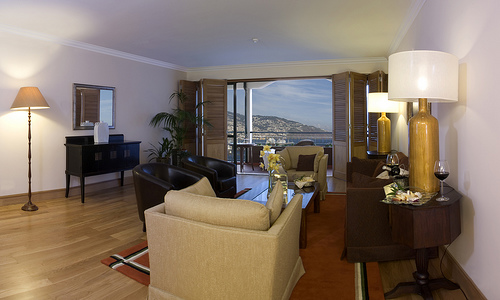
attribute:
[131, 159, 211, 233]
chair — leather, black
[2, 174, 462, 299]
floor — wood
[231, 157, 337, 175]
balcony — white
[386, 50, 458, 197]
lamp — tall, tan, gold, large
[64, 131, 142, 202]
cabinet — wooden, brown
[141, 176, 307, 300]
armchair — tan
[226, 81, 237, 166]
door — open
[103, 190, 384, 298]
rug — orange, striped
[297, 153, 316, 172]
pillow — dark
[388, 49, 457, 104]
shade — white